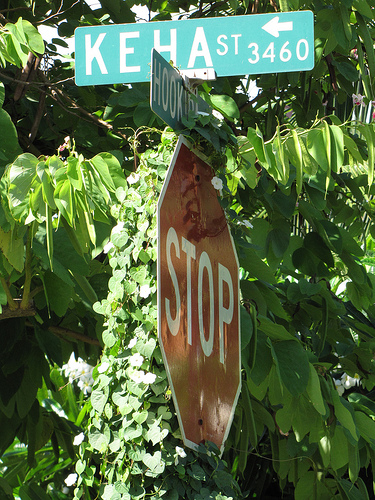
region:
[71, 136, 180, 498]
ivy growing on a pole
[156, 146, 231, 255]
grafitti in the dirt on the sign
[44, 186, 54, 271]
a bean pod on a limb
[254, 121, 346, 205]
a group of seed pods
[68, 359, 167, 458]
sunshine reflected on leaves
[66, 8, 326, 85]
keha street sign on a pole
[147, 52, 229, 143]
street sign that beings with HOOK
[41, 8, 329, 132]
two street signs above stop sign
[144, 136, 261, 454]
stop sign facing right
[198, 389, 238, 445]
reflection on face of stop sign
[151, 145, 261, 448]
Red and white stop sign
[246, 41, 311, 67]
6340 on the green sign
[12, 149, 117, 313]
green leaves beside the stop sign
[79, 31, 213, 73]
KEHA on the green sign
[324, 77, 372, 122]
red flowers between the leaves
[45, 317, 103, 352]
brown sticks between the leaves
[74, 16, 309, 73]
green and white sign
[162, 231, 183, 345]
letter s on the stop sign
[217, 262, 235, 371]
Letter p on the stop sign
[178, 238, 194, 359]
letter t on the stop sign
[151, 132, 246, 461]
red and white octagon sign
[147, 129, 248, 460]
red and white stop sign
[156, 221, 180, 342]
S of the STOP sign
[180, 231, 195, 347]
Letter T of the stop sign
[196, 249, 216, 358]
Letter O of the stop sign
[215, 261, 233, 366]
letter P of the STOP sign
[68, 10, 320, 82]
Green rectangular street sign on top of another green rectangular street sign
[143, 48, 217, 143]
green rectangular street sign below another green rectangular street sign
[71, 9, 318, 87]
Keha St Street sign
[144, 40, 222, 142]
Hook St Street sign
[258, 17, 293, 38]
White arrow on street sign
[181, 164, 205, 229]
Reflection on stop sign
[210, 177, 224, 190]
White flower growing by stop sign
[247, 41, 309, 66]
Set of numbers on street sign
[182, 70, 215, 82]
Bracket holding street signs together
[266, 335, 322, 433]
Large green leaves on plant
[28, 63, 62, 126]
Tree branches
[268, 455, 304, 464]
Vine growing with plants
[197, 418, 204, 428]
Black screw in stop sign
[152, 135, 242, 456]
A red stop sign with a white border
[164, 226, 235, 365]
Words written stop on a red background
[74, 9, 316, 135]
Two bluish directional signs mounted on one another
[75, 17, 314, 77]
Sign indicating Keha St is to the left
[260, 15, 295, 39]
White arrow on blue sign pointing left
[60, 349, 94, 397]
White flowers sticking out of a green background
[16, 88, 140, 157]
Shadow cast by the sun in the leaves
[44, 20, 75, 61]
The bright sky seen between the leaves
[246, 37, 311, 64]
The numbers three, four, six and zero on sign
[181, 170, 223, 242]
The shadow of leaves cast on the red sign